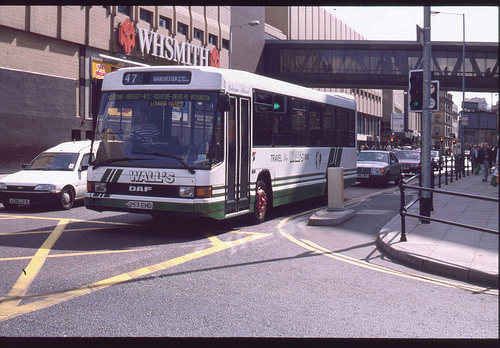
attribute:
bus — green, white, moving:
[71, 56, 373, 234]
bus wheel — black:
[254, 174, 274, 227]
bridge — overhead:
[254, 30, 498, 93]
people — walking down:
[464, 137, 499, 183]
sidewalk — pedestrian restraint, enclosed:
[374, 147, 499, 293]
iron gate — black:
[384, 146, 498, 250]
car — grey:
[359, 135, 412, 191]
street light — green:
[401, 64, 437, 223]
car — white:
[0, 130, 100, 214]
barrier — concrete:
[305, 161, 361, 231]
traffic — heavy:
[338, 129, 466, 188]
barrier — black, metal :
[366, 126, 472, 295]